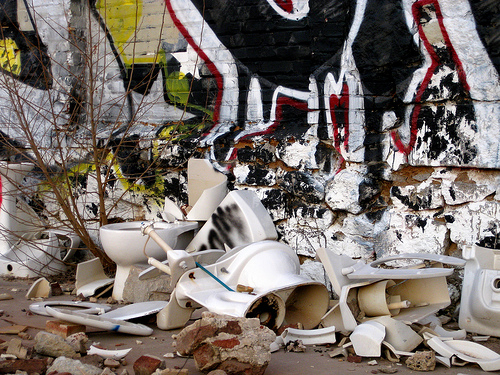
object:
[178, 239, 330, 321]
toilet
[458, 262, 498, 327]
sink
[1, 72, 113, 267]
tree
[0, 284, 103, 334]
ground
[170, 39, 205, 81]
star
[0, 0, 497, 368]
scene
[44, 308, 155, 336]
seat lids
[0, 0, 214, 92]
graffiti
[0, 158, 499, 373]
fixtures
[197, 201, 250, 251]
graffiti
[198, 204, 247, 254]
mom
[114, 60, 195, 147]
star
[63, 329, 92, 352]
rock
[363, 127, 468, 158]
graffiti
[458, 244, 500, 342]
urinal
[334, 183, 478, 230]
graffiti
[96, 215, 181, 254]
seat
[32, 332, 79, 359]
rock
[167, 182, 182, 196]
paint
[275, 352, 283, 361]
cement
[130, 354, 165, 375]
brick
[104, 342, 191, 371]
ground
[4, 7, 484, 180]
wall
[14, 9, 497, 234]
painting